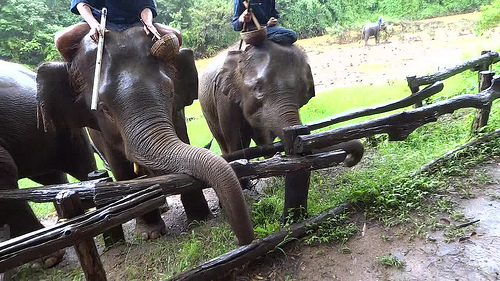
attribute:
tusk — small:
[128, 160, 145, 176]